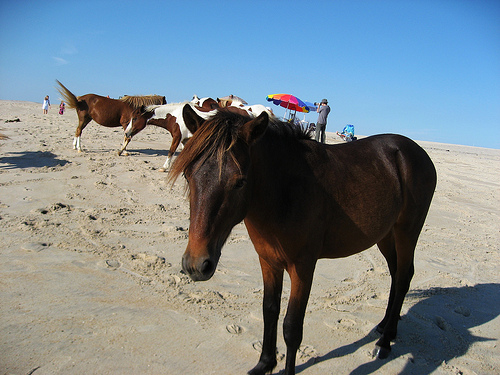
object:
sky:
[0, 0, 498, 150]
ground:
[0, 102, 497, 373]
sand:
[1, 103, 499, 375]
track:
[53, 203, 64, 212]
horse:
[168, 101, 438, 374]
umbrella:
[262, 92, 309, 113]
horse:
[55, 80, 167, 154]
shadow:
[0, 151, 71, 171]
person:
[41, 95, 51, 114]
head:
[166, 101, 269, 280]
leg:
[281, 255, 317, 369]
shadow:
[279, 282, 499, 374]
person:
[58, 101, 66, 115]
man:
[313, 98, 330, 142]